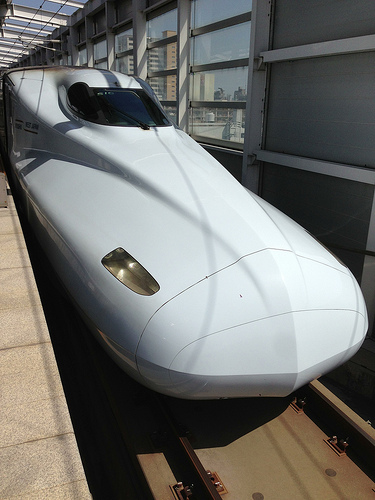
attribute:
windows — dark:
[65, 85, 174, 128]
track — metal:
[312, 376, 372, 478]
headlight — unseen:
[303, 228, 356, 282]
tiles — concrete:
[3, 172, 88, 498]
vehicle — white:
[3, 61, 373, 407]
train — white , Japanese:
[3, 61, 373, 406]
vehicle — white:
[2, 27, 365, 331]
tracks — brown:
[124, 402, 374, 492]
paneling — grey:
[260, 47, 374, 170]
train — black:
[23, 58, 259, 266]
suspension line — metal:
[31, 10, 53, 38]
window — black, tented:
[54, 81, 172, 127]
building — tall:
[120, 27, 185, 110]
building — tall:
[190, 65, 219, 118]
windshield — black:
[67, 79, 171, 128]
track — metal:
[308, 382, 363, 451]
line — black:
[167, 306, 370, 370]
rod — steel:
[142, 389, 222, 498]